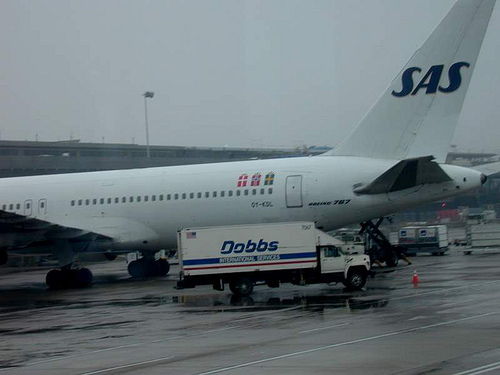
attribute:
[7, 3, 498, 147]
sky — grey, cloudy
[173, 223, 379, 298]
truck — cargo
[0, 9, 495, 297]
plane — stationary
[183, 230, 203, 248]
american flag — inverted 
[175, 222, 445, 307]
truck — white, red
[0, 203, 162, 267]
wing — horizontal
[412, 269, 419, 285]
cone — orange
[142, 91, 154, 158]
lamp — grey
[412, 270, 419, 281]
cone — orange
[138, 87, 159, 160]
pole — a light pole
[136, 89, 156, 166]
pole — lamp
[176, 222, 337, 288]
truck — white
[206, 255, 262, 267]
stripes — blue, red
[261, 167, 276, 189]
flag — international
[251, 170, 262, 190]
flag — international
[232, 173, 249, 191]
flag — international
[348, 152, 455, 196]
wing —  horizontal,  the Back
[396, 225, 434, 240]
boxes — white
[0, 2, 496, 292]
airplane — white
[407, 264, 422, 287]
cone — orange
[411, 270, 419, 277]
stripes — white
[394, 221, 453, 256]
luggage — carrier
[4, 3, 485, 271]
jet — large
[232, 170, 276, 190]
presents — three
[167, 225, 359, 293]
stripes — blue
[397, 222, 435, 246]
squares — blue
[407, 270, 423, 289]
dress — red